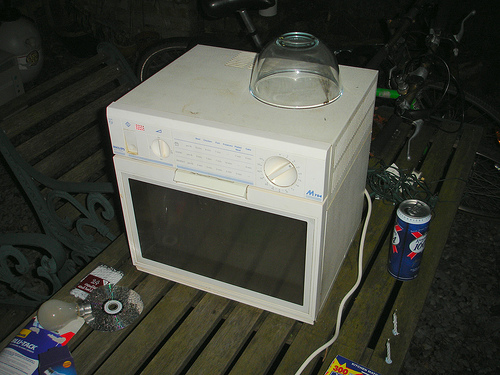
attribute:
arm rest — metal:
[1, 140, 116, 258]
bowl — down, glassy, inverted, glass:
[247, 28, 345, 108]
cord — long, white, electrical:
[276, 186, 382, 373]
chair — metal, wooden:
[2, 41, 142, 264]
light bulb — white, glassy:
[34, 297, 95, 331]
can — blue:
[378, 187, 451, 282]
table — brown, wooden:
[58, 291, 419, 373]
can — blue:
[385, 199, 432, 281]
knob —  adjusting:
[254, 144, 304, 204]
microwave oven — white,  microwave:
[103, 41, 380, 327]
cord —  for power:
[294, 187, 371, 372]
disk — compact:
[81, 278, 152, 326]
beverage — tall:
[385, 197, 434, 282]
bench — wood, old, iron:
[3, 44, 134, 251]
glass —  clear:
[250, 26, 352, 113]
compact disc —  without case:
[85, 283, 147, 333]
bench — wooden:
[429, 145, 465, 192]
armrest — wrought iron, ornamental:
[28, 172, 99, 255]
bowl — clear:
[248, 25, 349, 110]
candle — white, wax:
[383, 307, 403, 342]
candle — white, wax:
[379, 338, 392, 370]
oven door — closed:
[117, 160, 324, 327]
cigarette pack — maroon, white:
[67, 259, 128, 309]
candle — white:
[391, 309, 403, 338]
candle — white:
[387, 337, 392, 365]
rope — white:
[373, 295, 418, 362]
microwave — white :
[98, 41, 390, 329]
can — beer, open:
[361, 189, 489, 284]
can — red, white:
[382, 202, 431, 273]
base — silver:
[76, 303, 95, 319]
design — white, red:
[409, 227, 427, 259]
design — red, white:
[390, 220, 401, 251]